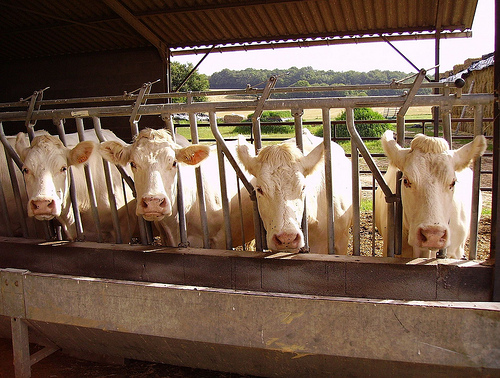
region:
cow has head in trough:
[14, 128, 144, 245]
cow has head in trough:
[98, 123, 265, 256]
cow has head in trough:
[235, 128, 357, 254]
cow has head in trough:
[368, 128, 487, 263]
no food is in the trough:
[2, 97, 498, 377]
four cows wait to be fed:
[12, 128, 489, 259]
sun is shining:
[164, 0, 497, 270]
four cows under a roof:
[1, 3, 479, 259]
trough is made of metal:
[4, 84, 499, 371]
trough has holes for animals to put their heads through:
[4, 57, 499, 377]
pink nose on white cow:
[414, 220, 451, 249]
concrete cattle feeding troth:
[192, 259, 461, 346]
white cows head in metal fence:
[374, 97, 474, 259]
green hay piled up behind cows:
[326, 104, 393, 138]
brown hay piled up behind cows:
[464, 54, 493, 133]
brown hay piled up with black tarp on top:
[465, 58, 493, 138]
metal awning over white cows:
[149, 2, 469, 60]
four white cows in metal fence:
[14, 133, 482, 250]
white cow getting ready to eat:
[244, 137, 329, 259]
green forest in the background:
[212, 69, 443, 91]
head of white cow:
[363, 115, 473, 255]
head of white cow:
[238, 124, 312, 266]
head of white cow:
[116, 128, 187, 234]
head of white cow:
[10, 133, 82, 238]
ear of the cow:
[71, 141, 95, 166]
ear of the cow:
[100, 136, 131, 165]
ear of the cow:
[173, 140, 213, 172]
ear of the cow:
[233, 140, 261, 185]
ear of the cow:
[294, 128, 324, 187]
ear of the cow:
[372, 124, 400, 174]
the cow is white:
[9, 114, 111, 262]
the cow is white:
[105, 115, 242, 281]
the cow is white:
[232, 128, 335, 290]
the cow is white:
[372, 118, 499, 295]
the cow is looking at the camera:
[19, 102, 82, 252]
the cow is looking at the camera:
[113, 123, 205, 260]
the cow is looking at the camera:
[218, 113, 348, 272]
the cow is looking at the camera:
[356, 88, 495, 270]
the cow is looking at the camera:
[127, 111, 217, 217]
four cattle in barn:
[32, 126, 469, 273]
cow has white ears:
[370, 130, 492, 180]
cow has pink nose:
[413, 205, 450, 267]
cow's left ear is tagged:
[172, 138, 237, 175]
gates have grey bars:
[63, 96, 422, 263]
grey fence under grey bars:
[12, 277, 460, 360]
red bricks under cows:
[19, 228, 471, 303]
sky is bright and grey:
[205, 44, 417, 76]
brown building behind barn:
[424, 55, 499, 158]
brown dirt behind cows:
[358, 220, 377, 255]